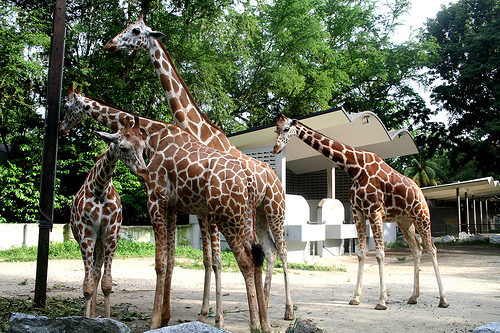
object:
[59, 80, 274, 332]
giraffe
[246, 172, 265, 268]
tail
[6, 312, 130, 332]
rocks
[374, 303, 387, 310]
hooves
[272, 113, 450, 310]
giraffe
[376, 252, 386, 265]
knees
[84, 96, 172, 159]
neck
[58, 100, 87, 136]
face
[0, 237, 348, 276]
grass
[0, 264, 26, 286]
dirt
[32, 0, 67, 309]
pole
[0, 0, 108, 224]
trees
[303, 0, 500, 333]
right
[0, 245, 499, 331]
bottom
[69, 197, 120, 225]
patch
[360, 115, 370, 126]
part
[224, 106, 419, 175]
roof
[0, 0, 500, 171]
sky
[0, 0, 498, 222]
background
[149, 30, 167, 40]
ear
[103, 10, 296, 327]
giraffes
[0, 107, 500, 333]
zoo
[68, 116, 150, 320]
giraffe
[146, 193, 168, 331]
legs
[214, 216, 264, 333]
legs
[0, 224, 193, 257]
fence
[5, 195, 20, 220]
wood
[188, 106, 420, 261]
shelter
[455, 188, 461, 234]
poles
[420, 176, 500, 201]
roof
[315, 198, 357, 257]
feeders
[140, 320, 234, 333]
stones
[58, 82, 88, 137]
head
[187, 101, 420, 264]
building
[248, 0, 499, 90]
leaves